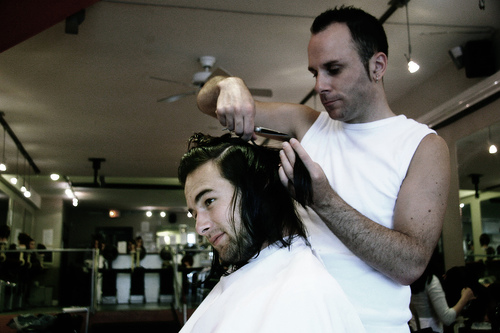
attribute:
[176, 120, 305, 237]
hair — cut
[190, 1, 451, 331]
hairdresser — male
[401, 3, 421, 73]
ceiling light — hanging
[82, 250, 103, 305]
hair dryer — white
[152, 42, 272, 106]
ceiling fan — white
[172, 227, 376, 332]
apron — white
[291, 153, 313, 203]
hair — black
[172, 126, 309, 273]
hair — black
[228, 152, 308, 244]
hair — black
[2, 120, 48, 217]
lights — hanging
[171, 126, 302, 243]
hair — black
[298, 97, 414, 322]
tank top — white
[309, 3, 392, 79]
hair — black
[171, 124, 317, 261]
hair — black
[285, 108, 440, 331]
shirt — white